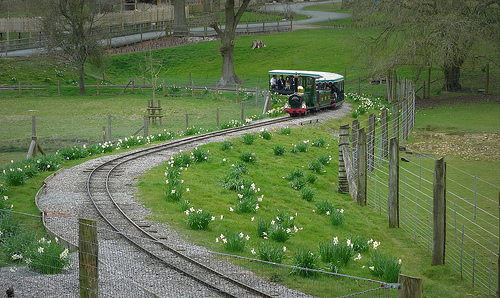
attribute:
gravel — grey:
[110, 248, 159, 295]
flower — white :
[329, 232, 363, 266]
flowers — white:
[0, 110, 405, 275]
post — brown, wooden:
[379, 136, 409, 235]